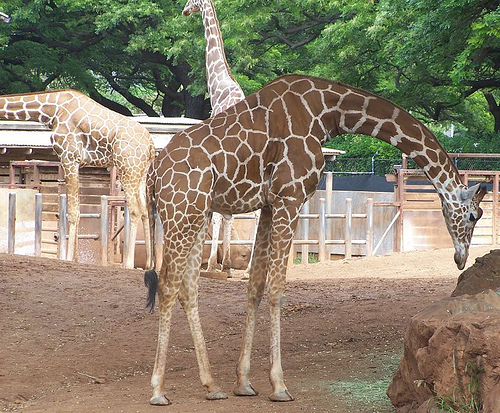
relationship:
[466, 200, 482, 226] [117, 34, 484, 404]
eye on giraffe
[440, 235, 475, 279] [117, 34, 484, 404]
mouth on giraffe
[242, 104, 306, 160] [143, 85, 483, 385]
pattern on a giraffe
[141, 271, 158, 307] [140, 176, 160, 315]
hair on end giraffe tail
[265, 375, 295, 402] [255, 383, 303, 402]
feet on feet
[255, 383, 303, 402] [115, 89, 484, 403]
feet of giraffe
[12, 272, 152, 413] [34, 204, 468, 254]
brown dirt ground along giraffe pen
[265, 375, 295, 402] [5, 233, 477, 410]
feet on ground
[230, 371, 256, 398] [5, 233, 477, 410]
hoof on ground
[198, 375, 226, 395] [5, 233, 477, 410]
hoof on ground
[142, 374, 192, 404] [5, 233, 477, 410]
hoof on ground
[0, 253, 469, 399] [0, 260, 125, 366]
ground covered in dirt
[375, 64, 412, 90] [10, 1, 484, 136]
leaves on tree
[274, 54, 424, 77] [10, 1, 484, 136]
leaves on tree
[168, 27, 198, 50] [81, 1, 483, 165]
leaves on tree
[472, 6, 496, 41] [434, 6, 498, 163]
leaves are growing on tree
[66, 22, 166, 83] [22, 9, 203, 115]
leaves are growing on tree